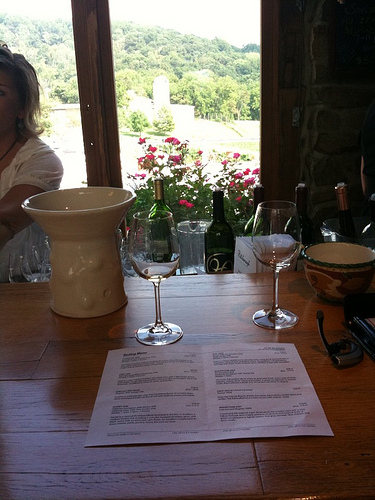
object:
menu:
[83, 342, 335, 448]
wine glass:
[250, 199, 301, 331]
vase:
[21, 188, 137, 320]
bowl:
[301, 241, 374, 303]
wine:
[203, 190, 235, 275]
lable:
[206, 250, 236, 276]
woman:
[0, 43, 65, 281]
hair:
[0, 45, 45, 137]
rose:
[163, 136, 182, 146]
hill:
[110, 23, 259, 121]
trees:
[114, 69, 260, 122]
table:
[0, 270, 374, 498]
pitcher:
[176, 218, 211, 275]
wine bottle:
[147, 179, 176, 262]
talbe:
[0, 269, 374, 498]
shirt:
[0, 137, 64, 279]